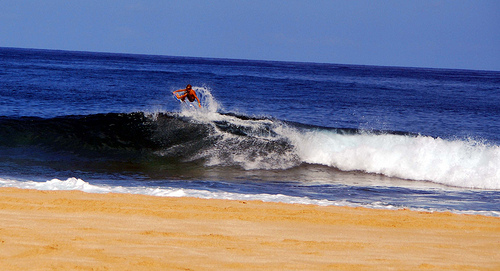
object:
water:
[0, 47, 500, 216]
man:
[171, 84, 202, 111]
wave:
[1, 109, 497, 189]